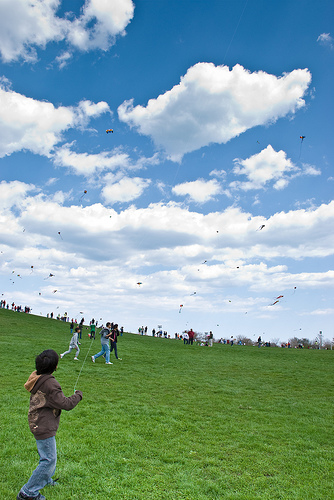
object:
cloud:
[1, 1, 134, 63]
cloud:
[115, 61, 312, 161]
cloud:
[0, 88, 112, 160]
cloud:
[234, 143, 297, 188]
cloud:
[0, 199, 333, 257]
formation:
[0, 0, 333, 348]